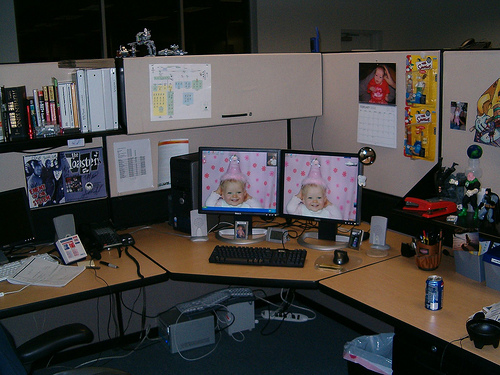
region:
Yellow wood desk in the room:
[2, 218, 499, 363]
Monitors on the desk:
[20, 141, 361, 226]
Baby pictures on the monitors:
[203, 152, 343, 220]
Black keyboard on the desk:
[205, 241, 306, 266]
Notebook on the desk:
[5, 252, 85, 283]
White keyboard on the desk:
[0, 253, 58, 283]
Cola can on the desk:
[423, 274, 444, 311]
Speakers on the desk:
[188, 209, 392, 251]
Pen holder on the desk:
[414, 238, 441, 271]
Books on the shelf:
[1, 83, 80, 140]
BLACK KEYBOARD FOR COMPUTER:
[211, 240, 311, 270]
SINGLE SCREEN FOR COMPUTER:
[190, 142, 283, 215]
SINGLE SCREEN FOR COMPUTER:
[280, 148, 363, 223]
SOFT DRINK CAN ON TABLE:
[424, 271, 446, 316]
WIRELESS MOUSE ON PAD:
[330, 245, 356, 270]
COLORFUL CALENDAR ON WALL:
[351, 59, 406, 155]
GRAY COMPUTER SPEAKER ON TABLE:
[367, 212, 390, 252]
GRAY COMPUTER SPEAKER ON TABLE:
[188, 205, 210, 245]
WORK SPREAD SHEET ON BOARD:
[143, 57, 218, 123]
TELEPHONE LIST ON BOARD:
[103, 133, 161, 193]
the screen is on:
[199, 150, 271, 208]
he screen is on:
[275, 151, 361, 222]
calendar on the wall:
[345, 59, 410, 152]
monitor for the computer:
[281, 140, 350, 220]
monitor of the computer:
[184, 135, 270, 210]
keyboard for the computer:
[207, 245, 297, 265]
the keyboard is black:
[232, 248, 300, 263]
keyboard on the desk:
[207, 246, 287, 265]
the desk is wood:
[362, 280, 386, 298]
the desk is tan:
[384, 289, 408, 303]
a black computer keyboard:
[206, 243, 305, 270]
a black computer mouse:
[331, 247, 348, 267]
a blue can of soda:
[426, 276, 443, 312]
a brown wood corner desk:
[0, 212, 499, 368]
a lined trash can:
[341, 332, 391, 374]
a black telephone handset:
[81, 221, 118, 259]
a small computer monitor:
[196, 144, 278, 242]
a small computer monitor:
[281, 146, 363, 253]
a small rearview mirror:
[356, 144, 378, 166]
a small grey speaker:
[366, 212, 390, 254]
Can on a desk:
[422, 268, 447, 313]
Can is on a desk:
[421, 268, 447, 321]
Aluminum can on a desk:
[421, 271, 444, 316]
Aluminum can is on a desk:
[420, 268, 449, 314]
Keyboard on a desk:
[207, 239, 311, 273]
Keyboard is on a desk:
[202, 239, 311, 272]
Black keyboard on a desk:
[206, 238, 306, 270]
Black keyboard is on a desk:
[205, 237, 310, 272]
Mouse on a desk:
[330, 245, 352, 269]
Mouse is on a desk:
[332, 239, 352, 271]